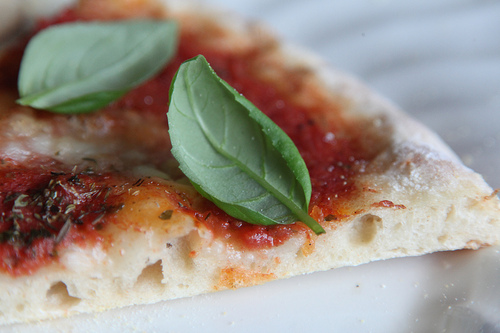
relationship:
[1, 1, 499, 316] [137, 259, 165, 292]
crust has bubble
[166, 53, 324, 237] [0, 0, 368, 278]
leaf on top of sauce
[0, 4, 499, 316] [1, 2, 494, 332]
pizza on top of plate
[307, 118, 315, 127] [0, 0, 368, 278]
pepper inside of sauce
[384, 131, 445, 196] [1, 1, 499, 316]
flour on top of crust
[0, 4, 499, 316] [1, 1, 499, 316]
pizza has crust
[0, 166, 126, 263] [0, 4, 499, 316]
dry herb on top of pizza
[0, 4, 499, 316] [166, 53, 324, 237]
pizza has leaf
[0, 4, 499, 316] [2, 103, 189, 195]
pizza has cheese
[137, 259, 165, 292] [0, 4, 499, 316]
bubble on side of pizza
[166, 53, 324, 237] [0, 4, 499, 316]
leaf on top of pizza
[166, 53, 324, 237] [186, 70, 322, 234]
leaf has stem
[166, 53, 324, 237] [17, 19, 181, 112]
leaf next to leaf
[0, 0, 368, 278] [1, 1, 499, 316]
sauce on top of crust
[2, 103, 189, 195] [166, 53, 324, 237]
cheese next to leaf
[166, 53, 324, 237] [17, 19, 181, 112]
leaf in front of leaf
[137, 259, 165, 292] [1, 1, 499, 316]
bubble inside crust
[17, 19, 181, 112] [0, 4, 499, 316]
leaf on top of pizza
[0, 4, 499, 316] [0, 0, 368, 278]
pizza has sauce